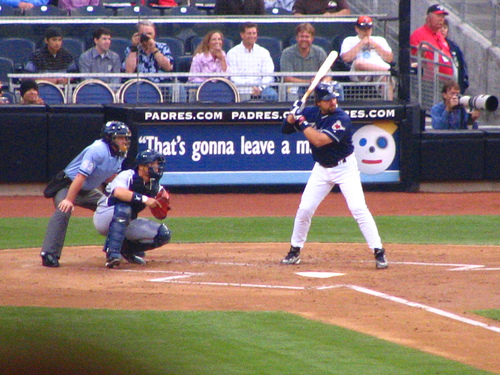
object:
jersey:
[281, 105, 355, 164]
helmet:
[313, 83, 339, 100]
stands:
[3, 0, 423, 194]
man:
[429, 80, 481, 130]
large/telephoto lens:
[459, 94, 498, 110]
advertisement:
[129, 110, 399, 186]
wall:
[1, 100, 419, 190]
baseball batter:
[278, 48, 390, 272]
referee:
[35, 118, 133, 268]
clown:
[350, 124, 397, 174]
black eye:
[376, 136, 388, 149]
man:
[121, 19, 173, 83]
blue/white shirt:
[120, 40, 175, 83]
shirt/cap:
[407, 4, 456, 80]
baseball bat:
[289, 50, 338, 115]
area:
[0, 302, 500, 375]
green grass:
[2, 306, 498, 375]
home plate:
[295, 271, 347, 279]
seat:
[197, 77, 242, 106]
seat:
[115, 76, 162, 104]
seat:
[69, 76, 116, 104]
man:
[410, 2, 458, 95]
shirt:
[407, 21, 455, 78]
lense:
[474, 95, 478, 108]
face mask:
[111, 134, 131, 152]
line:
[342, 282, 500, 335]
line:
[163, 280, 313, 290]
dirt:
[0, 238, 500, 371]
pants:
[289, 154, 384, 254]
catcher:
[89, 148, 178, 271]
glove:
[150, 196, 172, 220]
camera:
[139, 32, 149, 43]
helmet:
[105, 119, 131, 137]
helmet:
[134, 148, 162, 165]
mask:
[146, 157, 163, 179]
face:
[351, 125, 396, 174]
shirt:
[62, 139, 122, 185]